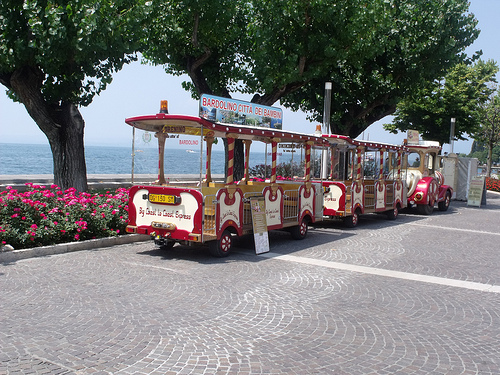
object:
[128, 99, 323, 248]
train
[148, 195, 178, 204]
plate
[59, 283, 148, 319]
ground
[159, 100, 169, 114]
light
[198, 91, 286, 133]
sign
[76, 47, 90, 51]
leaves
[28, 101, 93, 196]
trunk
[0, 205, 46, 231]
bushes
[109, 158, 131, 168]
water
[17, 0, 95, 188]
tree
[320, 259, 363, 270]
line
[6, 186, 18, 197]
flowers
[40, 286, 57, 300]
bricks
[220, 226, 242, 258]
tire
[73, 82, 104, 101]
branch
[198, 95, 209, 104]
words